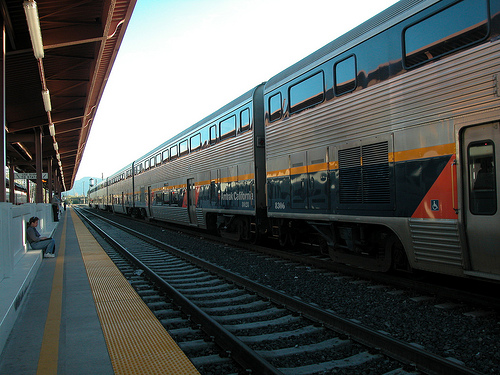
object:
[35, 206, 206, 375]
paint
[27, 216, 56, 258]
man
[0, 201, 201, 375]
platform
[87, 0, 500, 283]
amtrak train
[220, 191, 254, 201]
name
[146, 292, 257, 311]
tie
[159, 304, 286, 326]
tie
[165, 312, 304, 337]
tie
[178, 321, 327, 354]
tie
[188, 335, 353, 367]
tie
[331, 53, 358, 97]
window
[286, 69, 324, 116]
window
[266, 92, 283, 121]
window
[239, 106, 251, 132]
window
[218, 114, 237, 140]
window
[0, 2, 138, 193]
roof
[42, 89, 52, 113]
light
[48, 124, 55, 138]
light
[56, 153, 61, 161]
light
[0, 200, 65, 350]
bench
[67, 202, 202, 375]
line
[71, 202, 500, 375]
tracks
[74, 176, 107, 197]
mountain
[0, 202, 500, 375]
ground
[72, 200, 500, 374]
railroad rails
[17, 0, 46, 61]
light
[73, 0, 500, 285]
side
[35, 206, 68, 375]
line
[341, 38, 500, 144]
silver ridges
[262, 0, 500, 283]
train car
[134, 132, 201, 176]
windows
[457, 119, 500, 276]
door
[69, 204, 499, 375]
gravel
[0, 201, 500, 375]
floor